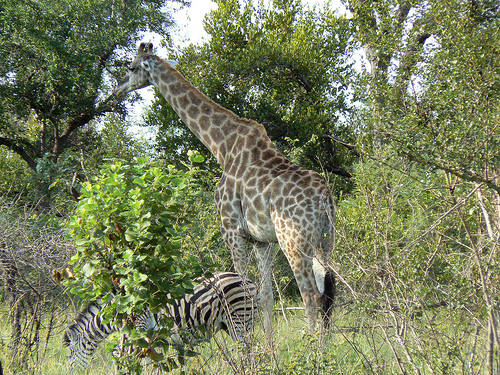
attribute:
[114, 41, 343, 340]
giraffe — tall, standing, brown, white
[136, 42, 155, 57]
horns — black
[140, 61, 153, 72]
ear — black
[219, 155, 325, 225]
spots — brown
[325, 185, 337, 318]
tail — long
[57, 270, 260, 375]
zebra — eating, black, white, gazing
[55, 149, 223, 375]
bush — green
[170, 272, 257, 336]
stripes — black, white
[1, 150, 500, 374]
foliage — green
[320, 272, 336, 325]
tail end — furry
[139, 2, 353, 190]
tree — tall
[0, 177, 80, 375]
bush — dry